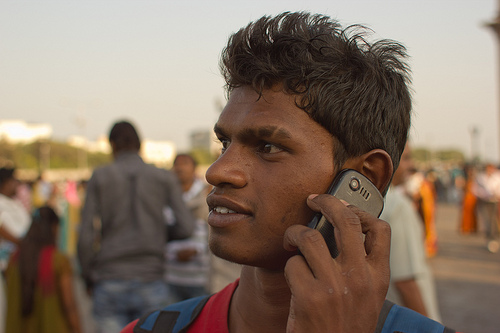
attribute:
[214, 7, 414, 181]
hair — black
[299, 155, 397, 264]
phone — silver, small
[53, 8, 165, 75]
sky — blue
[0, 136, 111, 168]
trees — green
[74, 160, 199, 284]
grey shirt — gray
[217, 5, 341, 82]
hair — curly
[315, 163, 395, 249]
phone — black